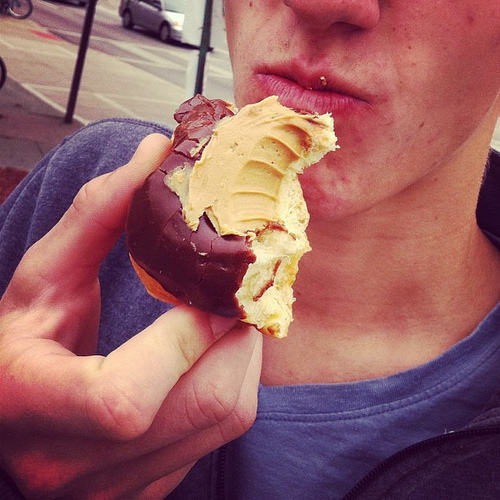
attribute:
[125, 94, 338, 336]
donut — eaten, half-eaten, frosted, pastry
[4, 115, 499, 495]
shirt — purple, blue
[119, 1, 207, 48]
sedan — grey, driving, silver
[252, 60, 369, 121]
lips — closed, red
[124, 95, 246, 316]
chocolate — brown, frosting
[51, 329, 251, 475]
finger — bent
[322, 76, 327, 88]
spots — small, white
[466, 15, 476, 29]
pimple — small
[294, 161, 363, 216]
chin — defined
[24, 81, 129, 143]
lines — white